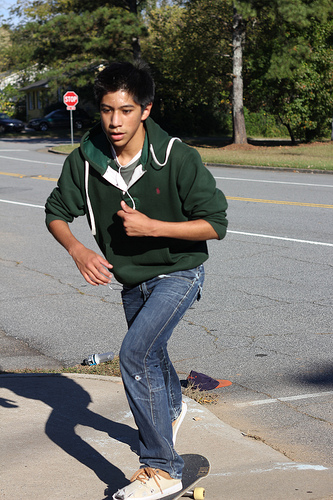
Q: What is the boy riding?
A: Skateboard.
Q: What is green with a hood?
A: The sweatshirt.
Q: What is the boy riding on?
A: Road.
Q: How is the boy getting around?
A: On a skateboard.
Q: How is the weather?
A: Sunny.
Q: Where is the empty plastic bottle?
A: On the ground.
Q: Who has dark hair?
A: The boy.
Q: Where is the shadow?
A: On the sidewalk.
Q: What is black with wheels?
A: Skateboard.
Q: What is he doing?
A: Skating.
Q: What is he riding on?
A: Skateboard.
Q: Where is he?
A: Street corner.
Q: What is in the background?
A: Trees.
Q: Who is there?
A: Young man.